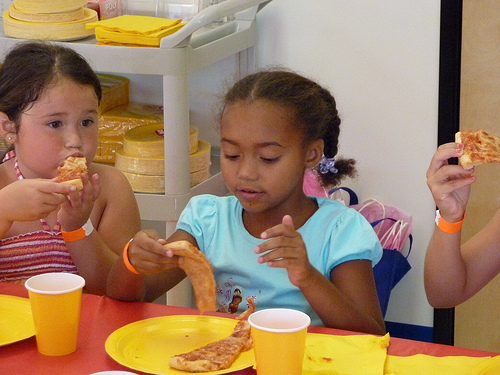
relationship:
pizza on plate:
[173, 298, 253, 373] [97, 307, 259, 372]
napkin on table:
[303, 331, 391, 373] [0, 285, 499, 372]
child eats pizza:
[106, 70, 386, 334] [41, 149, 91, 193]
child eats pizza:
[0, 40, 142, 295] [157, 233, 219, 313]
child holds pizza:
[106, 68, 390, 335] [165, 235, 217, 309]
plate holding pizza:
[103, 315, 260, 373] [168, 295, 263, 372]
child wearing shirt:
[106, 70, 386, 334] [202, 220, 287, 325]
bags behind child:
[336, 182, 421, 315] [106, 70, 386, 334]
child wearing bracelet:
[106, 70, 386, 334] [123, 238, 140, 275]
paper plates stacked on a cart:
[120, 120, 201, 156] [1, 2, 267, 293]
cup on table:
[24, 272, 86, 359] [0, 285, 499, 372]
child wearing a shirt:
[106, 70, 386, 334] [174, 194, 384, 328]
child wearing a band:
[106, 70, 386, 334] [55, 218, 98, 246]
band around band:
[55, 218, 98, 246] [59, 218, 94, 240]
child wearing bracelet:
[106, 70, 386, 334] [116, 243, 150, 262]